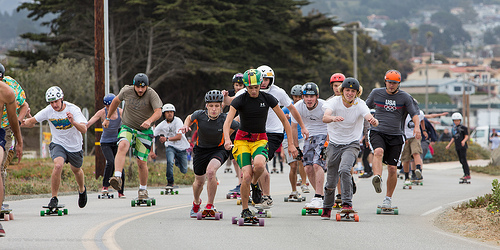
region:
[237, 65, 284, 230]
Boy wearing Bob Marley colors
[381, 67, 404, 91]
Man wearing orange helmet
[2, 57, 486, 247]
All the people are skateboarding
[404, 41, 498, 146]
Houses in the background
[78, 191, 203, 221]
Double yellow line in road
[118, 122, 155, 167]
Man in green shorts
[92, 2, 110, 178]
brown telephone in background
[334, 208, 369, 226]
Orange wheels on skateboard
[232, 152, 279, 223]
Boy wearing shorts skateboarding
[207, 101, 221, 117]
Boy looks determined on his skateboard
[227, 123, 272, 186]
red yellow and green shorts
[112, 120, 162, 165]
green and white shorts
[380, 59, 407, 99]
orange safety helmet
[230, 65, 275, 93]
red yellow and green safety helmet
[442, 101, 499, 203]
person skateboarding down street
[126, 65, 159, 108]
black safety helmet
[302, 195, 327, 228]
skateboad with green wheels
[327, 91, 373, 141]
boy wearing white short sleeve T shirt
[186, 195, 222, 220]
red tennis shoe strings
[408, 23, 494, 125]
city on hill side at a distance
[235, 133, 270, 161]
man wearing multi colored shorts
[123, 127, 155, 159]
man wearing multi colored shorts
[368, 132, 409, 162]
man wearing multi colored shorts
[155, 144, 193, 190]
man wearing multi colored shorts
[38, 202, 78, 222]
young man using skateboard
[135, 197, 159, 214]
young man using skateboard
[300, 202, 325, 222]
young man using skateboard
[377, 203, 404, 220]
young man using skateboard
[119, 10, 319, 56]
brown trees with green leaves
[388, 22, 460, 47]
brown trees with green leaves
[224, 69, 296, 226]
skateboarder in green and yellow helmet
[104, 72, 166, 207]
man in green shorts skateboarding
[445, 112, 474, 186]
boy in black t-shirt on skateboard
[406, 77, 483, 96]
tan and light blue house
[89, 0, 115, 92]
wooden pole for electrical wires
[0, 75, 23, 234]
man without shirt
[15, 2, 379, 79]
large fir trees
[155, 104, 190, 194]
boy in jeans riding skateboard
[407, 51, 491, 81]
tan houses with red trim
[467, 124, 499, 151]
a white truck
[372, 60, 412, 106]
orange and black helmet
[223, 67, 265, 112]
green red and yellow helmet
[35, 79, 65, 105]
white and gray helmet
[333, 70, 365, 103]
black and yellow helmet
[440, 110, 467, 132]
white helmet on person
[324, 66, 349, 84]
red and white helmet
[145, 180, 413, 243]
lots of skat boards on road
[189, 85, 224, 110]
black helmet with slots in it.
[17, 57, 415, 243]
people skate boarding on road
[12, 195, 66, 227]
green skateboard wheels with black deck